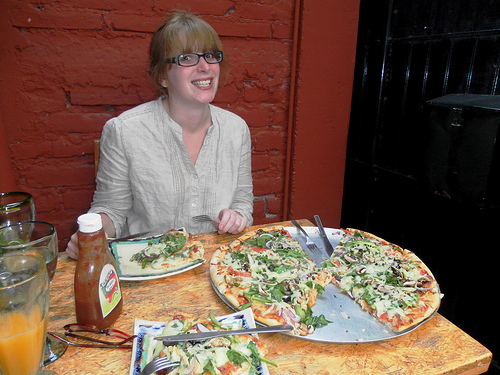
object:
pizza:
[206, 223, 440, 340]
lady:
[63, 11, 255, 264]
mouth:
[190, 78, 218, 90]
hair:
[144, 12, 226, 97]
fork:
[290, 216, 323, 256]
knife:
[313, 213, 336, 257]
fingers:
[218, 207, 231, 232]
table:
[0, 219, 493, 374]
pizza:
[129, 225, 200, 268]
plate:
[126, 306, 269, 375]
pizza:
[149, 311, 261, 373]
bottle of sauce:
[71, 213, 125, 331]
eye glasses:
[45, 320, 139, 349]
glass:
[0, 249, 48, 372]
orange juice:
[0, 311, 47, 373]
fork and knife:
[290, 213, 333, 259]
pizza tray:
[209, 223, 442, 344]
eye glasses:
[167, 49, 226, 66]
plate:
[110, 228, 208, 285]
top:
[74, 213, 103, 233]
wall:
[0, 0, 362, 252]